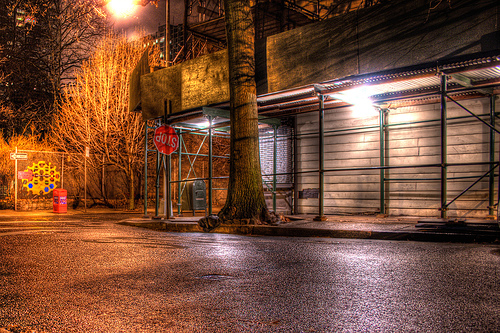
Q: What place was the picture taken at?
A: It was taken at the street.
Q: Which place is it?
A: It is a street.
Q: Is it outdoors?
A: Yes, it is outdoors.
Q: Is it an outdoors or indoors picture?
A: It is outdoors.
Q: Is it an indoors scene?
A: No, it is outdoors.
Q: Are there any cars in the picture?
A: No, there are no cars.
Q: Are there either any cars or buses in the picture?
A: No, there are no cars or buses.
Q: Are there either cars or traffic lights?
A: No, there are no cars or traffic lights.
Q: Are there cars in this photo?
A: No, there are no cars.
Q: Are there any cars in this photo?
A: No, there are no cars.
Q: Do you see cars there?
A: No, there are no cars.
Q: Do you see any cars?
A: No, there are no cars.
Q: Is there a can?
A: Yes, there is a can.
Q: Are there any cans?
A: Yes, there is a can.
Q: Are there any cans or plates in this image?
A: Yes, there is a can.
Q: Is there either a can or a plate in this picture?
A: Yes, there is a can.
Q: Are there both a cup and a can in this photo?
A: No, there is a can but no cups.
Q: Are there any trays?
A: No, there are no trays.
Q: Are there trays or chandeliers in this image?
A: No, there are no trays or chandeliers.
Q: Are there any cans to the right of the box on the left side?
A: Yes, there is a can to the right of the box.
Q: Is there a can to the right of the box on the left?
A: Yes, there is a can to the right of the box.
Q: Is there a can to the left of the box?
A: No, the can is to the right of the box.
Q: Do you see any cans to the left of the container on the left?
A: No, the can is to the right of the box.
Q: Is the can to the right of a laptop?
A: No, the can is to the right of the box.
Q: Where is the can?
A: The can is on the street.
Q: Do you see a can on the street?
A: Yes, there is a can on the street.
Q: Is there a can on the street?
A: Yes, there is a can on the street.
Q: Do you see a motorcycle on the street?
A: No, there is a can on the street.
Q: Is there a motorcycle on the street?
A: No, there is a can on the street.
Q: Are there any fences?
A: Yes, there is a fence.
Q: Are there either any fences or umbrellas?
A: Yes, there is a fence.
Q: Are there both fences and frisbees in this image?
A: No, there is a fence but no frisbees.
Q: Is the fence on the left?
A: Yes, the fence is on the left of the image.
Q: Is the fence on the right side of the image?
A: No, the fence is on the left of the image.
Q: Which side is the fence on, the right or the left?
A: The fence is on the left of the image.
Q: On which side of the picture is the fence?
A: The fence is on the left of the image.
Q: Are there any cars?
A: No, there are no cars.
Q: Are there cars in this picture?
A: No, there are no cars.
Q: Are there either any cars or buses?
A: No, there are no cars or buses.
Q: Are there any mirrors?
A: No, there are no mirrors.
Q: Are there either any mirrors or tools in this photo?
A: No, there are no mirrors or tools.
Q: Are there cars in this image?
A: No, there are no cars.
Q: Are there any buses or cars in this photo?
A: No, there are no cars or buses.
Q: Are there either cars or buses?
A: No, there are no cars or buses.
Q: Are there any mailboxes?
A: No, there are no mailboxes.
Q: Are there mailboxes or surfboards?
A: No, there are no mailboxes or surfboards.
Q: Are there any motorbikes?
A: No, there are no motorbikes.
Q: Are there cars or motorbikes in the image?
A: No, there are no motorbikes or cars.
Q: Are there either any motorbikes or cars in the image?
A: No, there are no motorbikes or cars.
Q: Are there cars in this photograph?
A: No, there are no cars.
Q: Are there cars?
A: No, there are no cars.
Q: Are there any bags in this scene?
A: No, there are no bags.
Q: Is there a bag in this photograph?
A: No, there are no bags.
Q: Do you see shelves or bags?
A: No, there are no bags or shelves.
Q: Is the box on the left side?
A: Yes, the box is on the left of the image.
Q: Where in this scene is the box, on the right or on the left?
A: The box is on the left of the image.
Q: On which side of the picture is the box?
A: The box is on the left of the image.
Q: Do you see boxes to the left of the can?
A: Yes, there is a box to the left of the can.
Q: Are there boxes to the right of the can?
A: No, the box is to the left of the can.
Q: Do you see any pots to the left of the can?
A: No, there is a box to the left of the can.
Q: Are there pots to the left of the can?
A: No, there is a box to the left of the can.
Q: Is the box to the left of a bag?
A: No, the box is to the left of the can.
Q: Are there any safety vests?
A: No, there are no safety vests.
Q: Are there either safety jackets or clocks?
A: No, there are no safety jackets or clocks.